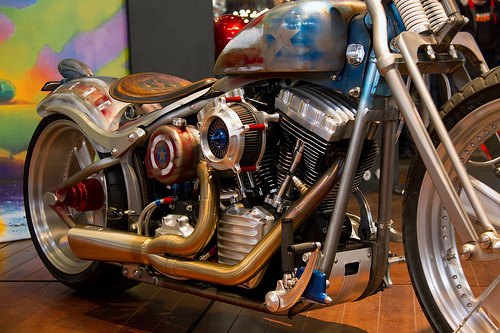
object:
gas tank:
[211, 0, 367, 79]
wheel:
[21, 113, 138, 295]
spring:
[423, 0, 448, 32]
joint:
[44, 175, 106, 212]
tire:
[21, 111, 127, 294]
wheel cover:
[33, 75, 133, 154]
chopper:
[212, 69, 366, 269]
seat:
[108, 72, 218, 104]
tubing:
[67, 161, 340, 287]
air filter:
[201, 96, 271, 173]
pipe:
[65, 227, 149, 265]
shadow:
[83, 284, 368, 333]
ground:
[0, 161, 499, 331]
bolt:
[344, 41, 364, 66]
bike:
[22, 0, 499, 333]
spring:
[393, 0, 430, 35]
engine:
[137, 74, 383, 290]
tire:
[400, 68, 499, 332]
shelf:
[212, 2, 233, 14]